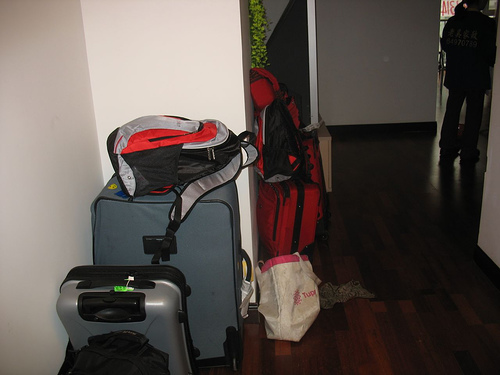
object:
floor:
[242, 131, 500, 374]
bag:
[254, 252, 319, 341]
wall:
[0, 0, 254, 371]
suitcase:
[54, 262, 195, 372]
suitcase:
[91, 173, 241, 363]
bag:
[66, 330, 174, 375]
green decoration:
[249, 0, 269, 67]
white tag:
[238, 277, 253, 318]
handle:
[238, 249, 252, 281]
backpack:
[107, 115, 260, 265]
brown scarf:
[319, 280, 374, 309]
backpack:
[255, 99, 309, 184]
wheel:
[232, 358, 240, 371]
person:
[439, 2, 496, 159]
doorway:
[437, 3, 483, 132]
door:
[250, 0, 310, 128]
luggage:
[257, 176, 318, 259]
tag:
[114, 286, 133, 292]